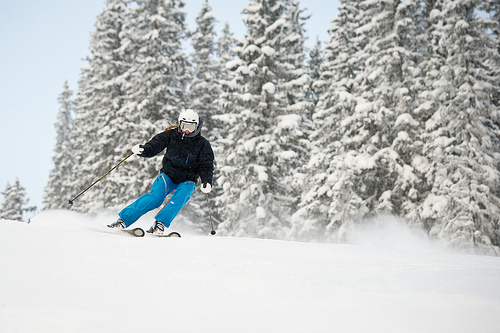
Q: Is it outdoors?
A: Yes, it is outdoors.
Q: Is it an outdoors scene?
A: Yes, it is outdoors.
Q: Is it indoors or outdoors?
A: It is outdoors.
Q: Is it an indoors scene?
A: No, it is outdoors.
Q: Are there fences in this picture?
A: No, there are no fences.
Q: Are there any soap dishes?
A: No, there are no soap dishes.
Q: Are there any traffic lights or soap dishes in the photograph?
A: No, there are no soap dishes or traffic lights.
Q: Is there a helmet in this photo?
A: Yes, there is a helmet.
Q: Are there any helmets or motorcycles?
A: Yes, there is a helmet.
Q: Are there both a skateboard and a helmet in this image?
A: No, there is a helmet but no skateboards.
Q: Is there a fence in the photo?
A: No, there are no fences.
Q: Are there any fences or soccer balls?
A: No, there are no fences or soccer balls.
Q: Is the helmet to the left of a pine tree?
A: Yes, the helmet is to the left of a pine tree.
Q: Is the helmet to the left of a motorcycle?
A: No, the helmet is to the left of a pine tree.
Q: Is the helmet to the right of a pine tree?
A: No, the helmet is to the left of a pine tree.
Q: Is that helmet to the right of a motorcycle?
A: No, the helmet is to the right of a pine tree.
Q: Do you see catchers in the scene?
A: No, there are no catchers.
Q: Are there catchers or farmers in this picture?
A: No, there are no catchers or farmers.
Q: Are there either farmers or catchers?
A: No, there are no catchers or farmers.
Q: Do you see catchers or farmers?
A: No, there are no catchers or farmers.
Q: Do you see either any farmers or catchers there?
A: No, there are no catchers or farmers.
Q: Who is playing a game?
A: The lady is playing a game.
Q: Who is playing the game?
A: The lady is playing a game.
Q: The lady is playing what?
A: The lady is playing a game.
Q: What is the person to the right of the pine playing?
A: The lady is playing a game.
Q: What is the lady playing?
A: The lady is playing a game.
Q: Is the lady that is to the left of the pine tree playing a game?
A: Yes, the lady is playing a game.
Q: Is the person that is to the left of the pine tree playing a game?
A: Yes, the lady is playing a game.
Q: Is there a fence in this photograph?
A: No, there are no fences.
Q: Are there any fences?
A: No, there are no fences.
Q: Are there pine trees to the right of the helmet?
A: Yes, there is a pine tree to the right of the helmet.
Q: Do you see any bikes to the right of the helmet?
A: No, there is a pine tree to the right of the helmet.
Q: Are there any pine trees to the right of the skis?
A: Yes, there is a pine tree to the right of the skis.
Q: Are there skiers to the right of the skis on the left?
A: No, there is a pine tree to the right of the skis.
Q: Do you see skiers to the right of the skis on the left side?
A: No, there is a pine tree to the right of the skis.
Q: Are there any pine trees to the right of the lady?
A: Yes, there is a pine tree to the right of the lady.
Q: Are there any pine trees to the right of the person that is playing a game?
A: Yes, there is a pine tree to the right of the lady.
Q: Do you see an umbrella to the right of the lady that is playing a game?
A: No, there is a pine tree to the right of the lady.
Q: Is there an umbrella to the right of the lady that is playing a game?
A: No, there is a pine tree to the right of the lady.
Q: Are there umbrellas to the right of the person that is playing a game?
A: No, there is a pine tree to the right of the lady.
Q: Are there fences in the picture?
A: No, there are no fences.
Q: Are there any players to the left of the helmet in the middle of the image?
A: No, there is a pine tree to the left of the helmet.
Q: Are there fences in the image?
A: No, there are no fences.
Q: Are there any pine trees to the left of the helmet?
A: Yes, there is a pine tree to the left of the helmet.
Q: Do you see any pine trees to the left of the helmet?
A: Yes, there is a pine tree to the left of the helmet.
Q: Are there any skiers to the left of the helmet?
A: No, there is a pine tree to the left of the helmet.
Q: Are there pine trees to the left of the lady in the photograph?
A: Yes, there is a pine tree to the left of the lady.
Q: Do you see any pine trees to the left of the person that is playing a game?
A: Yes, there is a pine tree to the left of the lady.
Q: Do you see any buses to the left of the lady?
A: No, there is a pine tree to the left of the lady.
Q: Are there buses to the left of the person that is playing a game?
A: No, there is a pine tree to the left of the lady.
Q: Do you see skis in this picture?
A: Yes, there are skis.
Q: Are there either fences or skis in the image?
A: Yes, there are skis.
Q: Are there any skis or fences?
A: Yes, there are skis.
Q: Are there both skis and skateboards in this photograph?
A: No, there are skis but no skateboards.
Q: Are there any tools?
A: No, there are no tools.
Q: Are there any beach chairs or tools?
A: No, there are no tools or beach chairs.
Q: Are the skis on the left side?
A: Yes, the skis are on the left of the image.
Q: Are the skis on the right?
A: No, the skis are on the left of the image.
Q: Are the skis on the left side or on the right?
A: The skis are on the left of the image.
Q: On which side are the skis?
A: The skis are on the left of the image.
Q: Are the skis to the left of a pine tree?
A: Yes, the skis are to the left of a pine tree.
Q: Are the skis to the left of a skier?
A: No, the skis are to the left of a pine tree.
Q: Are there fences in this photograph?
A: No, there are no fences.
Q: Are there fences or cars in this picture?
A: No, there are no fences or cars.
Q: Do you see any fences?
A: No, there are no fences.